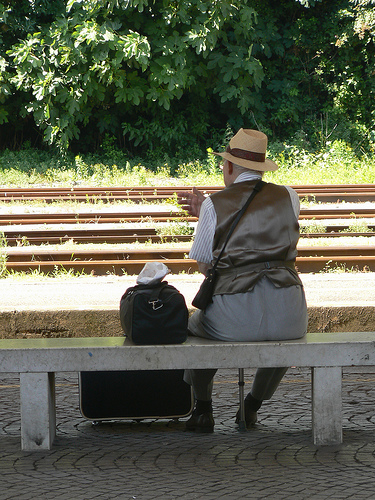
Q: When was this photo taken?
A: During the day.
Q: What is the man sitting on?
A: A bench.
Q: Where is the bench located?
A: In front of train tracks.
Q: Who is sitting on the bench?
A: A man.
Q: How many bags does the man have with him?
A: Two.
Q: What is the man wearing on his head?
A: A hat.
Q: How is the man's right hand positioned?
A: Bent at the elbow with his hand toward the right side of this body.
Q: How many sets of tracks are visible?
A: Three.